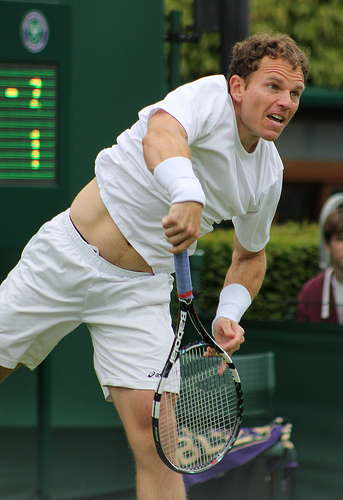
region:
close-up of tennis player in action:
[14, 29, 329, 435]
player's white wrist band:
[211, 281, 248, 320]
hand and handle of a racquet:
[159, 200, 198, 298]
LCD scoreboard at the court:
[0, 56, 62, 181]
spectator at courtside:
[294, 189, 339, 317]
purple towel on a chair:
[175, 424, 293, 479]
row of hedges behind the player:
[165, 0, 337, 77]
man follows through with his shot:
[81, 26, 311, 478]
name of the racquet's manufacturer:
[161, 305, 183, 359]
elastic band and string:
[64, 226, 103, 265]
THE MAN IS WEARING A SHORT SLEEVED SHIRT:
[87, 71, 294, 295]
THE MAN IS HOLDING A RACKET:
[143, 243, 249, 497]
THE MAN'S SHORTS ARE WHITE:
[0, 204, 190, 395]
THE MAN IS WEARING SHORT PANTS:
[1, 204, 197, 403]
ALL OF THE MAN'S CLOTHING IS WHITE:
[1, 63, 287, 405]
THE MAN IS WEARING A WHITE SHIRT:
[89, 73, 292, 284]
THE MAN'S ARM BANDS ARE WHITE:
[144, 151, 253, 339]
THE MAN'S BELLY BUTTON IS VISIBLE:
[121, 235, 136, 260]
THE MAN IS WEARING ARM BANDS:
[144, 151, 256, 327]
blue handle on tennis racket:
[164, 228, 199, 308]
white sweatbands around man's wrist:
[150, 149, 207, 227]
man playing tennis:
[5, 48, 323, 485]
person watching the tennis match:
[290, 202, 342, 330]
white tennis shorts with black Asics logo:
[2, 240, 185, 384]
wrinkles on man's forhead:
[216, 22, 318, 149]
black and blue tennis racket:
[134, 223, 249, 481]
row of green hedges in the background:
[144, 224, 341, 322]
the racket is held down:
[146, 220, 245, 474]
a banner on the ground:
[174, 416, 302, 485]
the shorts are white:
[0, 204, 188, 401]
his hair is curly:
[225, 28, 312, 86]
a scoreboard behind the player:
[0, 59, 68, 180]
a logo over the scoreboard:
[15, 4, 53, 55]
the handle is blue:
[168, 240, 192, 303]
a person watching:
[292, 191, 341, 332]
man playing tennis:
[1, 26, 311, 499]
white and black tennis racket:
[139, 306, 250, 477]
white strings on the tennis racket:
[164, 352, 235, 465]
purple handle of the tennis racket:
[174, 252, 198, 295]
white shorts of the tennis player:
[5, 217, 182, 397]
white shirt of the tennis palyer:
[96, 76, 287, 264]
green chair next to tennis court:
[174, 352, 294, 491]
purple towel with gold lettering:
[177, 418, 301, 481]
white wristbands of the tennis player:
[154, 156, 252, 318]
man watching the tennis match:
[297, 191, 342, 329]